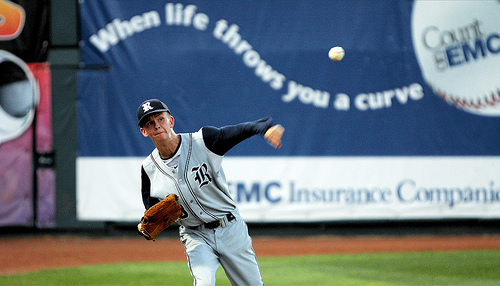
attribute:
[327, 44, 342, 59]
baseball — white, flying, being thrown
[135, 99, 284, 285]
pitcher — baseball player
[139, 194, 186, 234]
baseball glove — brown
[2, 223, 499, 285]
baseball field — green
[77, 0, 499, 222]
advertisement — blue, white, for insurance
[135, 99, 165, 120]
cap — navy blue, dark, black, white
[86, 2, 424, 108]
text — white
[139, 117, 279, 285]
uniform — gray, navy, black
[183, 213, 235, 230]
belt — black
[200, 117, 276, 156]
sleeve — dark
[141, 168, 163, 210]
sleeve — dark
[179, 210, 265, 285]
pants — light gray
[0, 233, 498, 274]
dirt — light brown, in outfield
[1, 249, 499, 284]
grass — green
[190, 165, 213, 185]
letter — r